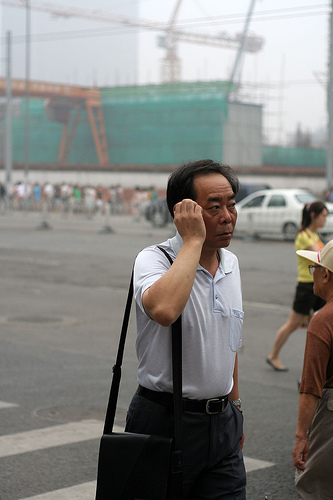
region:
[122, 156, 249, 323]
a man on a cell phone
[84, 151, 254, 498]
a man with a satchel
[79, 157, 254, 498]
a man in a white shirt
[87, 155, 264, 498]
a man in gray pants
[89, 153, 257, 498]
a man in grey pants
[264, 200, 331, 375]
a woman with a pony tail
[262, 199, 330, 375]
a girl in a yellow shirt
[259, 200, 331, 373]
a female pedestrian in black skirt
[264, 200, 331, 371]
a woman out for a stroll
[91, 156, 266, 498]
a man with a receding hairline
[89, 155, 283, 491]
A man walking and talking on cell phone.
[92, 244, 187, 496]
Man carrying black case over shoulder.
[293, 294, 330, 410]
Man wearing a brown shirt.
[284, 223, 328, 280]
Woman wearing yellow shirt.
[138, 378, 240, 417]
Black belt around man's waist.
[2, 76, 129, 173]
Orange structure in background.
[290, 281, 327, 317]
Woman wearing black shorts.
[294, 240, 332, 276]
Man wearing tan cap.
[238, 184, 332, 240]
White car parked on side of street.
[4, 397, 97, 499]
White lines of a pedestrian crosswalk.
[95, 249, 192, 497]
black purse on man's shoulder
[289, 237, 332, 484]
man with a tan hat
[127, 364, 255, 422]
black belt around waist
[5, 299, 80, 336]
manhole cover in street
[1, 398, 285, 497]
white lines on road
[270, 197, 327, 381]
brown haired woman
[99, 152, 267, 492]
dark haired man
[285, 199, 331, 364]
woman in yellow shirt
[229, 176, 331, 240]
white car in background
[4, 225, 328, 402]
asphalt paved road where people are walking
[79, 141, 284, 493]
an asian man walking on a street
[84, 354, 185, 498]
a black bag the man is carrying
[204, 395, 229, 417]
a silver belt buckle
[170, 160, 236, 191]
the man's receding hair line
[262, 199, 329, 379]
a woman with a yellow top in the background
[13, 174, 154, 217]
a large line of people in the background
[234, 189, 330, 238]
a white car in the background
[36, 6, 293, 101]
a crane in a construction area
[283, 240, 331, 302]
an old man with a cap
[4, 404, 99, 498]
white lines painted on the ground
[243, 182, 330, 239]
White car driving down the street.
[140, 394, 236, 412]
Black belt on man's pants wearing the light blue shirt.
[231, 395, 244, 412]
Watch on the man's wrist wearing the black pants.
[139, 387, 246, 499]
Black pants worn by the man in the light blue shirt.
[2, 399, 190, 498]
White crosswalk lines in the street.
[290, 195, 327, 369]
Woman walking in the yellow shirt.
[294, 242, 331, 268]
Tan hat worn by man in brown t-shirt.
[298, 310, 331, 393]
Brown sleeve of man's shirt in the hat.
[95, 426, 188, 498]
Messenger bag worn by man in the light blue shirt.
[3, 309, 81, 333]
Circular covered sewage hole in the street.